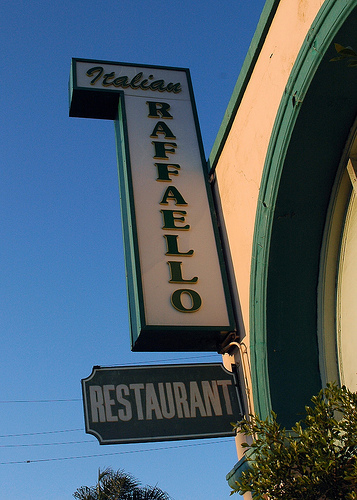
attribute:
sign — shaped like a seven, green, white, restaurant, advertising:
[71, 51, 241, 351]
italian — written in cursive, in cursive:
[83, 62, 185, 99]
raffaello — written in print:
[143, 93, 206, 314]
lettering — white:
[86, 375, 239, 426]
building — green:
[207, 0, 353, 464]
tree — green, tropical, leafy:
[230, 381, 356, 494]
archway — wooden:
[229, 0, 355, 429]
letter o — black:
[168, 284, 207, 314]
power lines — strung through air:
[0, 388, 233, 471]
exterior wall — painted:
[205, 3, 354, 499]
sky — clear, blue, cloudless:
[2, 0, 248, 500]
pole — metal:
[218, 329, 252, 425]